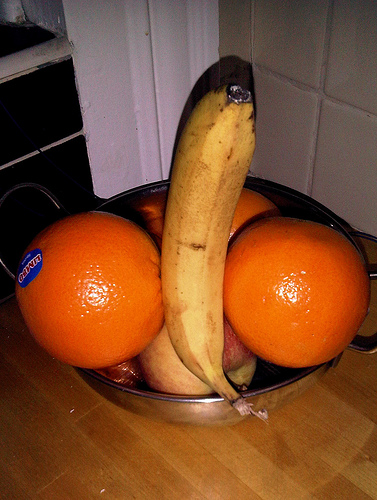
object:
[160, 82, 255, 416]
banana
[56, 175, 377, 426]
fruit bowl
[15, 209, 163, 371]
orange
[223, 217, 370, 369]
orange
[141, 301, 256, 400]
apple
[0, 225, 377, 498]
table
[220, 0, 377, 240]
wall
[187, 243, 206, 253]
dark spot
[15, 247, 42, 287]
red sticker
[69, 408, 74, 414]
spot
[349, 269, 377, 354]
handle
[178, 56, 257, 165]
shadow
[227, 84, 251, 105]
dark spot